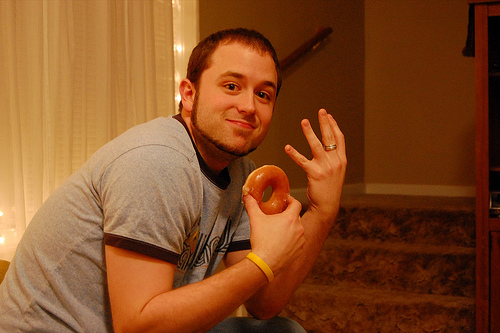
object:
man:
[0, 28, 346, 333]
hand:
[243, 196, 307, 275]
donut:
[242, 165, 290, 216]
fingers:
[301, 119, 329, 161]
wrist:
[246, 252, 280, 281]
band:
[246, 252, 274, 283]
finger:
[319, 109, 338, 157]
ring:
[324, 144, 337, 151]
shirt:
[0, 114, 256, 332]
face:
[194, 43, 277, 156]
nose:
[237, 89, 256, 116]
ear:
[179, 78, 196, 112]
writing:
[177, 215, 231, 270]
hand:
[285, 108, 348, 208]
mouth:
[225, 119, 256, 130]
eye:
[222, 81, 242, 93]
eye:
[255, 91, 270, 101]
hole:
[262, 186, 274, 203]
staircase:
[249, 189, 475, 332]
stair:
[247, 283, 476, 332]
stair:
[301, 236, 478, 297]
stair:
[296, 193, 478, 248]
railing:
[273, 26, 332, 72]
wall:
[196, 0, 365, 207]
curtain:
[0, 0, 174, 264]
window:
[0, 0, 198, 263]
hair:
[179, 27, 283, 111]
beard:
[190, 88, 258, 157]